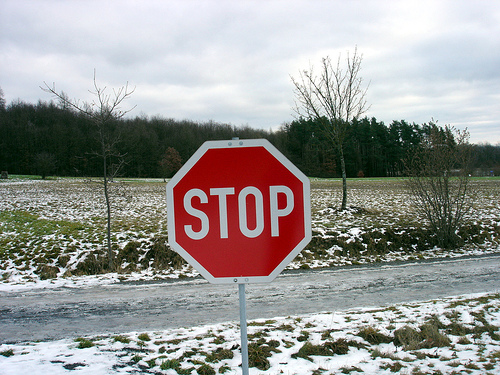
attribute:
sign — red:
[181, 145, 304, 296]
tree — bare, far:
[331, 94, 363, 141]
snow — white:
[358, 299, 393, 321]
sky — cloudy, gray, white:
[160, 18, 230, 59]